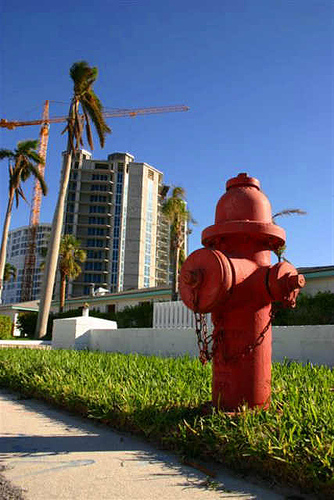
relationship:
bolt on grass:
[179, 171, 306, 410] [2, 345, 334, 489]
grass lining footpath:
[2, 358, 332, 467] [0, 389, 307, 498]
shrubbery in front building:
[269, 291, 332, 327] [29, 281, 331, 334]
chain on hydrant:
[193, 305, 281, 366] [193, 167, 322, 436]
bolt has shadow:
[179, 171, 306, 410] [3, 422, 164, 458]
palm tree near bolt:
[32, 59, 111, 339] [179, 171, 306, 410]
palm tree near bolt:
[0, 137, 48, 292] [179, 171, 306, 410]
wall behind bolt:
[55, 303, 330, 361] [179, 171, 306, 410]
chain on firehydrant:
[193, 305, 281, 366] [178, 163, 307, 404]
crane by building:
[2, 98, 189, 334] [6, 75, 273, 344]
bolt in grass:
[179, 171, 306, 410] [2, 345, 334, 489]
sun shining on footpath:
[0, 388, 333, 497] [0, 389, 307, 498]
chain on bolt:
[193, 305, 281, 366] [179, 171, 306, 410]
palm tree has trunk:
[32, 59, 111, 339] [33, 139, 74, 338]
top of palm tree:
[63, 60, 111, 156] [32, 59, 111, 339]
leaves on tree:
[2, 131, 54, 197] [2, 121, 37, 282]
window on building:
[10, 250, 19, 256] [10, 146, 179, 298]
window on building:
[6, 284, 15, 291] [10, 146, 179, 298]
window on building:
[42, 226, 47, 230] [10, 146, 179, 298]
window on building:
[10, 231, 22, 237] [10, 146, 179, 298]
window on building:
[16, 289, 21, 295] [10, 146, 179, 298]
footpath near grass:
[0, 389, 307, 498] [80, 343, 278, 455]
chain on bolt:
[182, 270, 221, 365] [179, 171, 306, 410]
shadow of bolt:
[1, 437, 147, 452] [179, 171, 306, 410]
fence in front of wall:
[152, 300, 213, 327] [88, 323, 333, 366]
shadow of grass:
[151, 394, 213, 434] [2, 345, 334, 489]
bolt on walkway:
[178, 455, 221, 477] [22, 433, 141, 485]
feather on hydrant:
[272, 203, 309, 220] [168, 167, 311, 404]